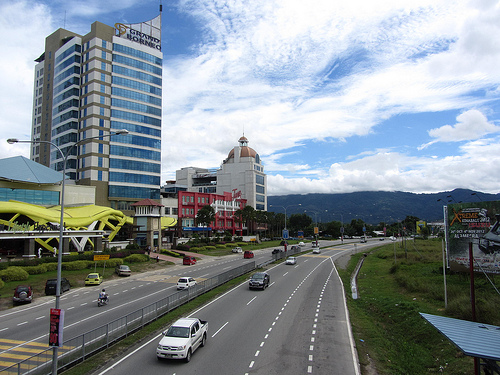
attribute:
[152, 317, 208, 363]
truck — white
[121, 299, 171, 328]
fence — gray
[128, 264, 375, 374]
road — paved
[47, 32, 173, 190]
building — blue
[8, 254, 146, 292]
cars — parked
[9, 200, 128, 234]
shed — yellow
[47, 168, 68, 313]
pole — gray